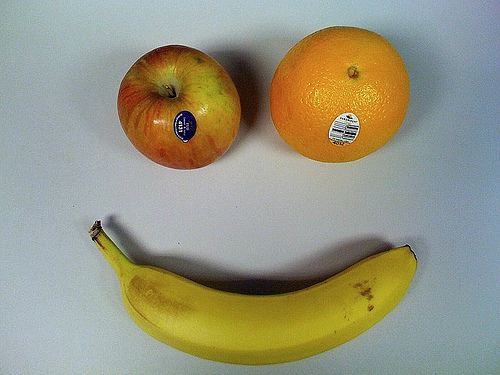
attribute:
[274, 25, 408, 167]
orange — navel, small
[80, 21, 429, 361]
food — white 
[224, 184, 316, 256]
surface — white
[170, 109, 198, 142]
sticker — purple, white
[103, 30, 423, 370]
fruit — fresh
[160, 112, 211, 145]
sticker — blue 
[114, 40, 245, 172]
red apple — small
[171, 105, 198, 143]
sticker — blue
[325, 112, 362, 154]
sticker — blue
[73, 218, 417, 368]
banana — yellow, ripe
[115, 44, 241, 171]
apples — red 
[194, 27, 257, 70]
shadows — light, dark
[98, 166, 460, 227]
table — white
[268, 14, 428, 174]
orange — bright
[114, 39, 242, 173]
apple — red, on top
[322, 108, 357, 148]
sticker — orange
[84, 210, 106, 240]
stem — brown